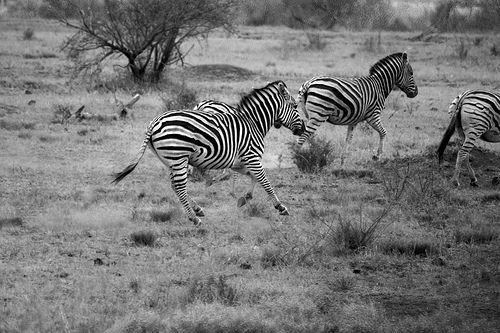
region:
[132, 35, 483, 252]
zebras running on field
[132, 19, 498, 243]
several zebras on a field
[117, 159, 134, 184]
black bushy tail of zebra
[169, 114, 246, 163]
white and black striped zebra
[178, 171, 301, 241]
zebras feet off of the ground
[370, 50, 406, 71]
black main of zebra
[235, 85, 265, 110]
black mane on zebra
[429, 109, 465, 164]
small tail of zebra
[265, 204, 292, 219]
black hoof of zebra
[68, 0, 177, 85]
small barren tree in field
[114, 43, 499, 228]
A group of zebra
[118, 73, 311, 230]
A zebra jumping up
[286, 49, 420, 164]
A zebra running away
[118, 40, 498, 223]
Group of zebra running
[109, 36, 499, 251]
Group of zebra on safari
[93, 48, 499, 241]
Group of zebras in jungle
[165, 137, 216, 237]
A zebras back legs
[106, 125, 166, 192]
A long zebra tail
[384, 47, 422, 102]
A zebras front snout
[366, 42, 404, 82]
Black and white zebra mane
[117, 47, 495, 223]
a group of zebras running.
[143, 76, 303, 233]
a zebra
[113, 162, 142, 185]
the zebras tail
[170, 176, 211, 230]
back legs of the zebra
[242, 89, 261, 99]
the zebras hair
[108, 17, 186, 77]
tree branches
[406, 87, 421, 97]
the zebras mouth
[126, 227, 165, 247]
patches of grass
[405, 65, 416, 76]
eye on the zebra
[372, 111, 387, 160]
front leg of the zebra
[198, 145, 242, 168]
the zebras stomach